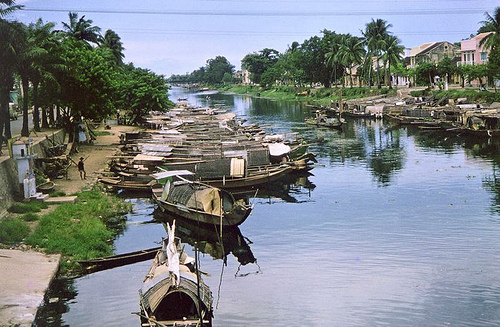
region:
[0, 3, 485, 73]
blue of daytime sky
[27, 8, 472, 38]
lines suspended in the sky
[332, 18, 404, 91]
leaves on palm trees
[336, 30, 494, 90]
houses overlooking water canal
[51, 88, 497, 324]
calm body of water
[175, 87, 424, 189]
reflection of trees on water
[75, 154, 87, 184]
person on paved river bank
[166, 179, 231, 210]
cover on boat cabin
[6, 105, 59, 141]
street behind tree trunk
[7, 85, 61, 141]
row of tree trunks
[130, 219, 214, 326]
Boat in the foreground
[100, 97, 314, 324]
Boats parked near shore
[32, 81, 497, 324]
River through the town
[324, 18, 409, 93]
Group of palm trees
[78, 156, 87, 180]
Man standing on shore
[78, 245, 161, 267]
The canoe is thin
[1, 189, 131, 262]
Grass on the shore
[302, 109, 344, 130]
Man sailing a boat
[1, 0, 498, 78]
The weather is clear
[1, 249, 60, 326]
A cement out cropping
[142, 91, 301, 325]
many boats in the water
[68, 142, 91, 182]
person standing on the edge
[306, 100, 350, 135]
people in the boat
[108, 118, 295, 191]
boats are docked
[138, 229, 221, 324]
boat coming in opposite direction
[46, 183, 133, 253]
greens in between dock and water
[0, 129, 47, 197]
objects leaning by the wall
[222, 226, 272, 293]
reflection of boat in water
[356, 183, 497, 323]
water is calm and blue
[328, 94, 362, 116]
people along the edge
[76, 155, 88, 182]
Man walking along dock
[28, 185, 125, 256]
Grass growing on dock and water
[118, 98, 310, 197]
Boats docked in the water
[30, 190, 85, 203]
Steps leading to a dock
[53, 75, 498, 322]
River water between two banks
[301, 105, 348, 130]
Boat sailing on the river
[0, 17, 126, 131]
Trees lining the road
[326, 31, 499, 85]
Buildings near the river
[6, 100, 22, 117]
Vehicle on the street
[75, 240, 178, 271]
Small canoe docked on the river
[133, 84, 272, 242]
these are the boats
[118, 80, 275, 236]
the boats are parked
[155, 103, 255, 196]
the boats are wooden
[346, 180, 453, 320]
the water is calm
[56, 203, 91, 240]
these are the grass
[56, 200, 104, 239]
the grass re green in color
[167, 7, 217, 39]
this is the sky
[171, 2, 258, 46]
the sky is clear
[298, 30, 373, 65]
these are the trees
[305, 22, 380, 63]
the trees are tall